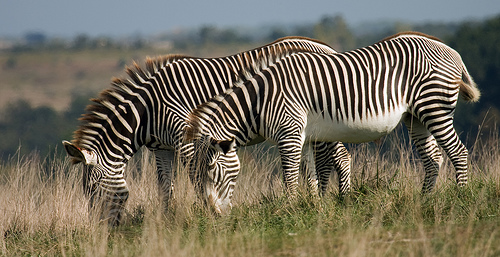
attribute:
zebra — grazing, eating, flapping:
[179, 31, 480, 228]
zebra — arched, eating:
[59, 47, 205, 227]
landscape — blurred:
[2, 5, 121, 155]